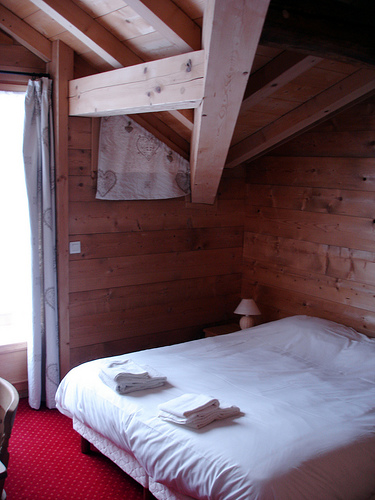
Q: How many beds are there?
A: One.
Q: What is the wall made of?
A: Wood.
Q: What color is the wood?
A: Brown.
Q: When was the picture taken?
A: Daytime.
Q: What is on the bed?
A: Towels.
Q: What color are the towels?
A: White.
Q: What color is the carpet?
A: Red.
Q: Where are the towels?
A: On the bed.